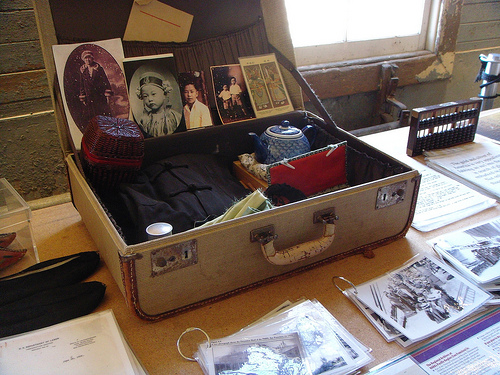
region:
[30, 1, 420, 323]
Opened carrying case on desktop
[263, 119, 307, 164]
Blue and white ceramic jar with a lid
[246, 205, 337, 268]
Handle of carrying case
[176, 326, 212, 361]
Silver ring through stack of pictures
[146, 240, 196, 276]
Right lock of carrying case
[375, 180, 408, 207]
Carrying cases lock on the left side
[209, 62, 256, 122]
Two children in a photo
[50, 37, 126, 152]
Picture of lady with a hat and coat on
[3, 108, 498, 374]
Tabletop with items sitting on it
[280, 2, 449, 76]
bottom part of white window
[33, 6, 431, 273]
an old suitcase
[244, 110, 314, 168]
a tiny blue teapot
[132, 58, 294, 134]
old photos of family members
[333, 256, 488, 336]
old photos on keyrings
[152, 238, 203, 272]
a rusty keyhole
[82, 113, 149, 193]
a small red wicker box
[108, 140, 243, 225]
a traditional black shirt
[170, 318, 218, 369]
A keyring used to bind things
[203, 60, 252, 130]
an old photo of two children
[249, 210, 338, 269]
an old cracked suitcase handle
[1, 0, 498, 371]
an old suitcase over a counter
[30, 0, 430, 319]
suitcase is brown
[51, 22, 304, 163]
pictures in a suitcase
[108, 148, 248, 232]
a black cloth in a suitcase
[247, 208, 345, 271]
handle of suitcase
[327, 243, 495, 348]
pictures hold in a ring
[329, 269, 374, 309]
a silver ring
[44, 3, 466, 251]
a window behind a suitcase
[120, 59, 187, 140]
black and white picture of toddler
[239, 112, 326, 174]
a blue teapot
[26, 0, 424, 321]
old-fashioned suitcase with momentos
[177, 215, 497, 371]
photographs in plastic connected to rings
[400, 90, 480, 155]
small and dark abacus on papers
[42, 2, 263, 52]
brown envelope in fabric pocket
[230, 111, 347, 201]
blue and white teapot next to red lid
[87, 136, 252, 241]
black folded garment folded on side of suitcase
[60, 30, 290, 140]
photographs lined along bottom of lid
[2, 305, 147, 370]
white paper with business letterhead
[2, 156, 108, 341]
black slippers next to plastic case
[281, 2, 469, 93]
window with worn wooden sill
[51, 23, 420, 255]
some photos in the briefcase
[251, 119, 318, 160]
a blue color jar in the brief case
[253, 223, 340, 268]
a handle of the briefcase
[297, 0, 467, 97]
window of the building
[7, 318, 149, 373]
some papers kept in the table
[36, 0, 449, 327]
a brown colour briefcase with many things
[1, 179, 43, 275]
some box near the briefcare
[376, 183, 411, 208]
a lock of the briefcase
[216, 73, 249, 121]
boys old photography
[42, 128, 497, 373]
many papers and a briefcase